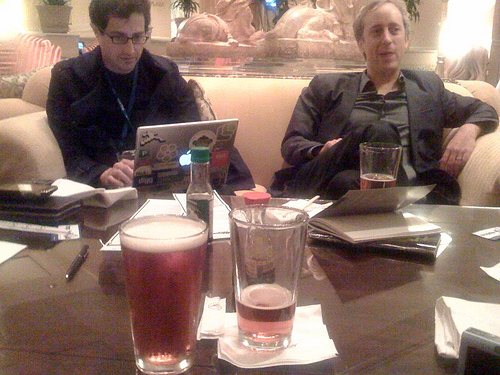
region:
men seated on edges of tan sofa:
[35, 3, 496, 200]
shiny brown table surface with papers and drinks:
[2, 190, 497, 367]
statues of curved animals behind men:
[145, 0, 360, 65]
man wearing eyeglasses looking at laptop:
[40, 0, 237, 186]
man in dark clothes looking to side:
[280, 0, 495, 205]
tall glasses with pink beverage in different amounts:
[110, 200, 305, 365]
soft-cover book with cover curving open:
[310, 180, 445, 245]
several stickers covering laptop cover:
[120, 120, 240, 190]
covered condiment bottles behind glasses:
[182, 137, 273, 282]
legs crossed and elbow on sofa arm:
[271, 11, 496, 201]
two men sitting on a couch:
[0, 0, 498, 209]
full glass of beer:
[122, 210, 207, 371]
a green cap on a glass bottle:
[188, 144, 211, 164]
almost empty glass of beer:
[225, 199, 310, 358]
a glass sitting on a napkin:
[212, 200, 342, 372]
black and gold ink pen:
[58, 238, 91, 280]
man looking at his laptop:
[46, 1, 260, 204]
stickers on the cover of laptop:
[135, 119, 240, 191]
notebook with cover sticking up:
[307, 180, 445, 252]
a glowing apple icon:
[177, 145, 194, 170]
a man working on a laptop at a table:
[41, 1, 262, 198]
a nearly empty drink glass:
[226, 197, 310, 351]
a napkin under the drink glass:
[218, 303, 340, 368]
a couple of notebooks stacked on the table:
[309, 184, 447, 266]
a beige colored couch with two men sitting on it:
[0, 63, 499, 210]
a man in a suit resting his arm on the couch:
[266, 0, 498, 202]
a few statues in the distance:
[167, 0, 358, 57]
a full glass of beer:
[116, 215, 210, 372]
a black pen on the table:
[66, 243, 91, 281]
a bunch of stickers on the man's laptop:
[131, 118, 238, 193]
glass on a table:
[226, 202, 312, 347]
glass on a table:
[116, 202, 202, 370]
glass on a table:
[355, 135, 410, 187]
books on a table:
[316, 189, 448, 261]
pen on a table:
[60, 242, 92, 293]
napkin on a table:
[305, 325, 345, 363]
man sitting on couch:
[310, 5, 470, 140]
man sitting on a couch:
[36, 5, 191, 112]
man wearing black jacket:
[285, 0, 476, 140]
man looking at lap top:
[37, 3, 252, 143]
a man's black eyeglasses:
[102, 28, 152, 46]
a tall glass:
[223, 195, 308, 353]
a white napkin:
[214, 303, 338, 365]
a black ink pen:
[56, 240, 95, 285]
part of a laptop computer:
[123, 115, 240, 184]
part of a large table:
[2, 187, 497, 372]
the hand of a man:
[436, 132, 473, 179]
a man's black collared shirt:
[352, 65, 417, 180]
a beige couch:
[0, 66, 498, 213]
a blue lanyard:
[105, 63, 145, 151]